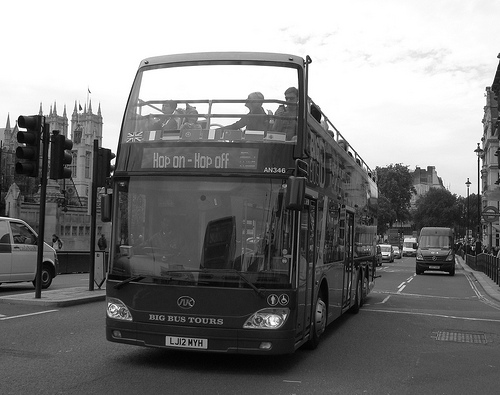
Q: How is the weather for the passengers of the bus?
A: Overcast.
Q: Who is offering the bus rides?
A: Big Ben Tours.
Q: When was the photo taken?
A: Late morning.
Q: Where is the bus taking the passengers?
A: Sightseeing.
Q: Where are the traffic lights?
A: To the left of the bus.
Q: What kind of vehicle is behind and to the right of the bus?
A: Delivery van.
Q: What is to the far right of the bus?
A: Old building.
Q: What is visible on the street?
A: The bus.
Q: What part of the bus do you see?
A: The front.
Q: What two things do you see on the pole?
A: Traffic lights.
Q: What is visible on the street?
A: A bus.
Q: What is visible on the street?
A: A bus.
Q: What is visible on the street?
A: A bus.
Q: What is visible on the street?
A: A bus.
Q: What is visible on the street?
A: A bus.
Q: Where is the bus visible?
A: On the street.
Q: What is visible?
A: A bus.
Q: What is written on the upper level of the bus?
A: Hop on - Hop off.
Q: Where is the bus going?
A: A bus tour.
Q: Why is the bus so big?
A: It has two levels.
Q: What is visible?
A: Bus.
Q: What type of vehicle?
A: Bus.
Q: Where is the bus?
A: On road.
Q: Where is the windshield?
A: On bus.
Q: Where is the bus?
A: On street.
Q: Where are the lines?
A: On road.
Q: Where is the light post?
A: On median.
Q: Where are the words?
A: On bus.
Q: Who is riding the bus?
A: Passengers.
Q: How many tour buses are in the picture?
A: One.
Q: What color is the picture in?
A: Black and white.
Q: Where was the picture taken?
A: On the street.